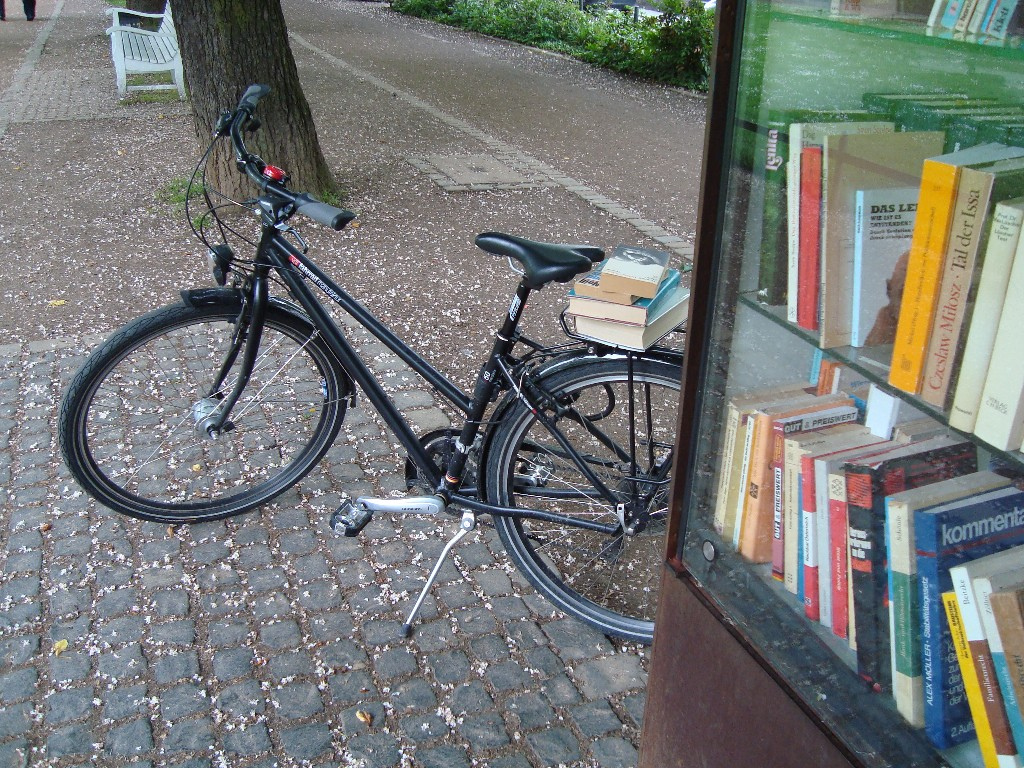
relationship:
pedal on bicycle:
[325, 482, 445, 538] [59, 86, 690, 640]